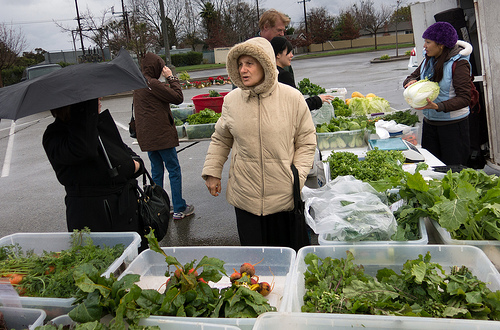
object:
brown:
[146, 108, 164, 128]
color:
[149, 136, 179, 146]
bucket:
[117, 244, 295, 329]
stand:
[0, 230, 500, 328]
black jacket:
[40, 108, 146, 231]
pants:
[234, 207, 311, 255]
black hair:
[271, 37, 296, 55]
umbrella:
[0, 48, 155, 123]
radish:
[236, 257, 265, 276]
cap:
[422, 22, 459, 48]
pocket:
[284, 160, 301, 193]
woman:
[400, 23, 484, 167]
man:
[256, 7, 290, 39]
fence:
[309, 35, 416, 54]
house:
[357, 19, 413, 37]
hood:
[137, 50, 164, 81]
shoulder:
[273, 83, 303, 99]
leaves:
[342, 249, 357, 260]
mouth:
[240, 75, 253, 83]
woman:
[200, 36, 318, 247]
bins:
[290, 243, 500, 323]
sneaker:
[173, 203, 195, 217]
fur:
[261, 55, 273, 83]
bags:
[134, 158, 171, 244]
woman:
[42, 100, 150, 254]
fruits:
[403, 78, 442, 111]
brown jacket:
[133, 51, 185, 152]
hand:
[161, 65, 172, 80]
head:
[135, 50, 161, 81]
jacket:
[199, 35, 318, 217]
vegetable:
[349, 90, 367, 98]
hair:
[428, 42, 461, 82]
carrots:
[9, 275, 30, 283]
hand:
[294, 169, 308, 195]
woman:
[133, 52, 193, 220]